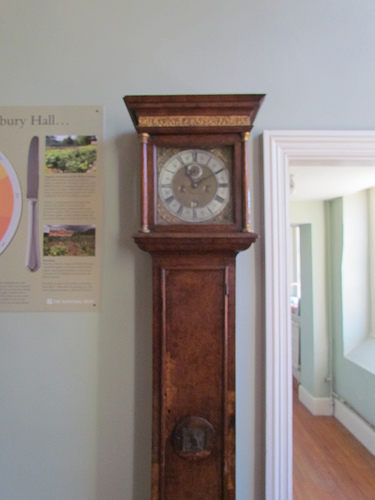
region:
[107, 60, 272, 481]
grandfather clock against wall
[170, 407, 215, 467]
grey square within a circle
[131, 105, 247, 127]
gold trim across top of clock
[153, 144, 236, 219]
roman numerals in white ring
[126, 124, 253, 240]
wooden dowels along side of clock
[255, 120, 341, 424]
white molding around doorway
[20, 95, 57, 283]
silver knife depicted on a poster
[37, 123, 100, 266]
pictures of homes and gardens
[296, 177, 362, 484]
hallway painted a greenish blue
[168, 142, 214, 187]
circle at the top of a circle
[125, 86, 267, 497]
Old grandfather clock focal point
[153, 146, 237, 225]
Ornamental bronze clock face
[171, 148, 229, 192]
Roman numerals time 11:10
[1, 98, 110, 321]
Poster plate knife green veg fields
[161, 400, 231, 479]
Indistinguishable round wood object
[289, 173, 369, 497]
Hallway painted light green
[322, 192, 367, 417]
Thick electrical wiring wall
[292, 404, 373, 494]
Wood floor boards hall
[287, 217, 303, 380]
Room window down hall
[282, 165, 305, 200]
Hanging light bulb fixture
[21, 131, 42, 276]
Butter knife printed on poster on the wall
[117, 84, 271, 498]
Old grandfather clock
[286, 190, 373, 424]
Green walls in the next room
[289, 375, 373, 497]
Hard wood floors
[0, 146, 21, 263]
Edge of a bowl on the poster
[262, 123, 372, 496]
Door frame next to the clock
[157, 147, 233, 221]
The face of the clock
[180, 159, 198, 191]
The hour hand of the clock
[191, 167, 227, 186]
The minute hand of the clock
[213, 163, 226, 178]
number the minute hand is pointing at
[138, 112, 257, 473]
this is a clock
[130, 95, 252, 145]
the frame is brown in color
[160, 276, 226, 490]
the stand is wooden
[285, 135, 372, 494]
the door is opened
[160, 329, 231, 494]
the stand is rusty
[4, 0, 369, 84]
the wall is white in color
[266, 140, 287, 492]
the doorstep is white in color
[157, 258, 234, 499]
the stand is straight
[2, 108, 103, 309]
this is post beside the clock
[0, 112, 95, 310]
the magazine post is brown in color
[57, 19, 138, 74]
the wall is white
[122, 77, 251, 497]
the clock is tall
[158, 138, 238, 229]
the clock is circle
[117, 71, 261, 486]
the clock is brown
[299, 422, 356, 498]
the floor is brown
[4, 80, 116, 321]
the poster is peach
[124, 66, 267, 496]
the clock is wooden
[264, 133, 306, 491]
the door edge is white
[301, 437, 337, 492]
the floor is wooden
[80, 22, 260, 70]
the wall is smooth